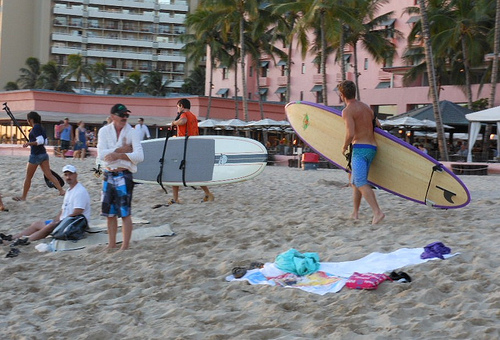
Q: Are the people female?
A: No, they are both male and female.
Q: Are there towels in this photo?
A: Yes, there is a towel.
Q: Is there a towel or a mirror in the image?
A: Yes, there is a towel.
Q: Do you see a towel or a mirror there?
A: Yes, there is a towel.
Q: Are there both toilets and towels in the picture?
A: No, there is a towel but no toilets.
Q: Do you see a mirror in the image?
A: No, there are no mirrors.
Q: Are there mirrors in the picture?
A: No, there are no mirrors.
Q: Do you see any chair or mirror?
A: No, there are no mirrors or chairs.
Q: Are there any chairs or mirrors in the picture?
A: No, there are no mirrors or chairs.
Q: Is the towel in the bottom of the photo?
A: Yes, the towel is in the bottom of the image.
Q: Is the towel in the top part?
A: No, the towel is in the bottom of the image.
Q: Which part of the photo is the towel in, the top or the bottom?
A: The towel is in the bottom of the image.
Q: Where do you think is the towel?
A: The towel is on the sand.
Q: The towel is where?
A: The towel is on the sand.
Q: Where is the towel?
A: The towel is on the sand.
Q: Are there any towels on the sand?
A: Yes, there is a towel on the sand.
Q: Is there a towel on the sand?
A: Yes, there is a towel on the sand.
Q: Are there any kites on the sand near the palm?
A: No, there is a towel on the sand.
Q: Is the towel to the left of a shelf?
A: No, the towel is to the left of the bag.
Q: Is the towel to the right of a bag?
A: No, the towel is to the left of a bag.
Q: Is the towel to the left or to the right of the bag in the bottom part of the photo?
A: The towel is to the left of the bag.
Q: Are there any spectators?
A: No, there are no spectators.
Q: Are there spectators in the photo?
A: No, there are no spectators.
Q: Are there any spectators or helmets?
A: No, there are no spectators or helmets.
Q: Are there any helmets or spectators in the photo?
A: No, there are no spectators or helmets.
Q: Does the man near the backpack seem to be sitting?
A: Yes, the man is sitting.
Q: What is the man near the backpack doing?
A: The man is sitting.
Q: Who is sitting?
A: The man is sitting.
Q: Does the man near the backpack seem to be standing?
A: No, the man is sitting.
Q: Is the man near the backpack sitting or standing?
A: The man is sitting.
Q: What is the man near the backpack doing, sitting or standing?
A: The man is sitting.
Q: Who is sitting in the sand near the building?
A: The man is sitting in the sand.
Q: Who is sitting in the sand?
A: The man is sitting in the sand.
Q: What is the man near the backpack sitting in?
A: The man is sitting in the sand.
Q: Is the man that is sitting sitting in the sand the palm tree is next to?
A: Yes, the man is sitting in the sand.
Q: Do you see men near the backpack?
A: Yes, there is a man near the backpack.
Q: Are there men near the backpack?
A: Yes, there is a man near the backpack.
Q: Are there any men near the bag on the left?
A: Yes, there is a man near the backpack.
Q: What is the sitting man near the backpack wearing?
A: The man is wearing a hat.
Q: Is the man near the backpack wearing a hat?
A: Yes, the man is wearing a hat.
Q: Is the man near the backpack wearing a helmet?
A: No, the man is wearing a hat.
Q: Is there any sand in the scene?
A: Yes, there is sand.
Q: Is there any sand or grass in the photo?
A: Yes, there is sand.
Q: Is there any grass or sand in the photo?
A: Yes, there is sand.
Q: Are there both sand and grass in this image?
A: No, there is sand but no grass.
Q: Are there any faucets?
A: No, there are no faucets.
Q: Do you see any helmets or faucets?
A: No, there are no faucets or helmets.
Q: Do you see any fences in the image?
A: No, there are no fences.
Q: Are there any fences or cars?
A: No, there are no fences or cars.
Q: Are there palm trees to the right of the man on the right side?
A: Yes, there is a palm tree to the right of the man.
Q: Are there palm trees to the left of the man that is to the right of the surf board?
A: No, the palm tree is to the right of the man.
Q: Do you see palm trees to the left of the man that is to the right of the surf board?
A: No, the palm tree is to the right of the man.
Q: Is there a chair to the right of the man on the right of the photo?
A: No, there is a palm tree to the right of the man.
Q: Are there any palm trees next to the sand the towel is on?
A: Yes, there is a palm tree next to the sand.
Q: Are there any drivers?
A: No, there are no drivers.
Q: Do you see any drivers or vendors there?
A: No, there are no drivers or vendors.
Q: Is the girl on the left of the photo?
A: Yes, the girl is on the left of the image.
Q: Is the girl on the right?
A: No, the girl is on the left of the image.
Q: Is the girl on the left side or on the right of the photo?
A: The girl is on the left of the image.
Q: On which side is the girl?
A: The girl is on the left of the image.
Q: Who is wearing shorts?
A: The girl is wearing shorts.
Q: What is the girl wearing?
A: The girl is wearing shorts.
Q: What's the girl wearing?
A: The girl is wearing shorts.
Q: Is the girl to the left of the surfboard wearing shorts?
A: Yes, the girl is wearing shorts.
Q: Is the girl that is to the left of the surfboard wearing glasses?
A: No, the girl is wearing shorts.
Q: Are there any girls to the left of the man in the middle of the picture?
A: Yes, there is a girl to the left of the man.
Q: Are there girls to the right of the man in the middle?
A: No, the girl is to the left of the man.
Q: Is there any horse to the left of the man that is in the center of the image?
A: No, there is a girl to the left of the man.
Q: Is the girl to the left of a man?
A: Yes, the girl is to the left of a man.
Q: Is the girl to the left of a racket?
A: No, the girl is to the left of a man.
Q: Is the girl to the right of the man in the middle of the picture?
A: No, the girl is to the left of the man.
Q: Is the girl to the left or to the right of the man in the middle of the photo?
A: The girl is to the left of the man.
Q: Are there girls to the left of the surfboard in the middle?
A: Yes, there is a girl to the left of the surfboard.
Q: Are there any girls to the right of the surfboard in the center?
A: No, the girl is to the left of the surfboard.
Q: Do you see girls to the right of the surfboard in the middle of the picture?
A: No, the girl is to the left of the surfboard.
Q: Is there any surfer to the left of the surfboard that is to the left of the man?
A: No, there is a girl to the left of the surfboard.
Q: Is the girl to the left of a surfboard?
A: Yes, the girl is to the left of a surfboard.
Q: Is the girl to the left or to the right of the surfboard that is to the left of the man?
A: The girl is to the left of the surfboard.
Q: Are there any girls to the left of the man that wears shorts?
A: Yes, there is a girl to the left of the man.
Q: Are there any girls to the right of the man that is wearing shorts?
A: No, the girl is to the left of the man.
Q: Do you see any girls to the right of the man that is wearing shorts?
A: No, the girl is to the left of the man.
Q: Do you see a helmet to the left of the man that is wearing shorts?
A: No, there is a girl to the left of the man.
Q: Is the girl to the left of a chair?
A: No, the girl is to the left of a man.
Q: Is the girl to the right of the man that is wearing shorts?
A: No, the girl is to the left of the man.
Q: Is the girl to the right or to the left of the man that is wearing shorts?
A: The girl is to the left of the man.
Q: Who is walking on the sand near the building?
A: The girl is walking on the sand.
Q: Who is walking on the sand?
A: The girl is walking on the sand.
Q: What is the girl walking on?
A: The girl is walking on the sand.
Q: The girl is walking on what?
A: The girl is walking on the sand.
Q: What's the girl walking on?
A: The girl is walking on the sand.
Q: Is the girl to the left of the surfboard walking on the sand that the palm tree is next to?
A: Yes, the girl is walking on the sand.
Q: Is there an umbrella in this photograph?
A: Yes, there is an umbrella.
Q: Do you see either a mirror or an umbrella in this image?
A: Yes, there is an umbrella.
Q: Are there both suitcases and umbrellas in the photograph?
A: No, there is an umbrella but no suitcases.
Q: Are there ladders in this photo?
A: No, there are no ladders.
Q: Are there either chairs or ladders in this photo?
A: No, there are no ladders or chairs.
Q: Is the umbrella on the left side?
A: No, the umbrella is on the right of the image.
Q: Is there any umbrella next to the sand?
A: Yes, there is an umbrella next to the sand.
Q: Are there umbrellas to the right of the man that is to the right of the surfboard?
A: Yes, there is an umbrella to the right of the man.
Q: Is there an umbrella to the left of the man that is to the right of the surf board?
A: No, the umbrella is to the right of the man.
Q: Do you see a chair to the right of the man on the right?
A: No, there is an umbrella to the right of the man.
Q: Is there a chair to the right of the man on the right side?
A: No, there is an umbrella to the right of the man.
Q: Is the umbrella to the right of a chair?
A: No, the umbrella is to the right of a man.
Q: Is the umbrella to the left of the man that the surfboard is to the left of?
A: No, the umbrella is to the right of the man.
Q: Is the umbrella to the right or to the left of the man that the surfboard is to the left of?
A: The umbrella is to the right of the man.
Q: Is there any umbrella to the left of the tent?
A: Yes, there is an umbrella to the left of the tent.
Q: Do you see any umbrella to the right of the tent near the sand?
A: No, the umbrella is to the left of the tent.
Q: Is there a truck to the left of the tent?
A: No, there is an umbrella to the left of the tent.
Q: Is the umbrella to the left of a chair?
A: No, the umbrella is to the left of the tent.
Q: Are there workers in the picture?
A: No, there are no workers.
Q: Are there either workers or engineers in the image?
A: No, there are no workers or engineers.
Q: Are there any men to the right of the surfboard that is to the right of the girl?
A: Yes, there is a man to the right of the surf board.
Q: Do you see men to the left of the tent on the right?
A: Yes, there is a man to the left of the tent.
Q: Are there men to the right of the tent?
A: No, the man is to the left of the tent.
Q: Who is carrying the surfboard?
A: The man is carrying the surfboard.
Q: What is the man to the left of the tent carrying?
A: The man is carrying a surf board.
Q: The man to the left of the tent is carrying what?
A: The man is carrying a surf board.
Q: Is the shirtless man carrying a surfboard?
A: Yes, the man is carrying a surfboard.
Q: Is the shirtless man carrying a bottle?
A: No, the man is carrying a surfboard.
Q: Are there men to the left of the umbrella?
A: Yes, there is a man to the left of the umbrella.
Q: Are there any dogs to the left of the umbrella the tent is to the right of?
A: No, there is a man to the left of the umbrella.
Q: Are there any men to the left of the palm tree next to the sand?
A: Yes, there is a man to the left of the palm.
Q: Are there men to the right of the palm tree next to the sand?
A: No, the man is to the left of the palm tree.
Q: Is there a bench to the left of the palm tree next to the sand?
A: No, there is a man to the left of the palm tree.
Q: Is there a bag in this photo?
A: Yes, there is a bag.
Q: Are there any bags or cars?
A: Yes, there is a bag.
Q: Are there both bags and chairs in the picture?
A: No, there is a bag but no chairs.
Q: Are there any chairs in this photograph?
A: No, there are no chairs.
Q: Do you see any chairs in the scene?
A: No, there are no chairs.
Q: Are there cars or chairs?
A: No, there are no chairs or cars.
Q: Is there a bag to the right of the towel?
A: Yes, there is a bag to the right of the towel.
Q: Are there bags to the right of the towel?
A: Yes, there is a bag to the right of the towel.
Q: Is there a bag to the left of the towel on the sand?
A: No, the bag is to the right of the towel.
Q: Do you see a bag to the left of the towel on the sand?
A: No, the bag is to the right of the towel.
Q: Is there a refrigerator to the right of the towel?
A: No, there is a bag to the right of the towel.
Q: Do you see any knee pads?
A: No, there are no knee pads.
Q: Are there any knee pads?
A: No, there are no knee pads.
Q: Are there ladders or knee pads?
A: No, there are no knee pads or ladders.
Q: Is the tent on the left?
A: No, the tent is on the right of the image.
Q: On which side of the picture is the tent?
A: The tent is on the right of the image.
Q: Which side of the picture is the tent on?
A: The tent is on the right of the image.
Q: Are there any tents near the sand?
A: Yes, there is a tent near the sand.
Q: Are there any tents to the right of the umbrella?
A: Yes, there is a tent to the right of the umbrella.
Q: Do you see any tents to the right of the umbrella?
A: Yes, there is a tent to the right of the umbrella.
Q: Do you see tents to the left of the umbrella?
A: No, the tent is to the right of the umbrella.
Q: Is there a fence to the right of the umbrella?
A: No, there is a tent to the right of the umbrella.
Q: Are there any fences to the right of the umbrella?
A: No, there is a tent to the right of the umbrella.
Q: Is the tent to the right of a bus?
A: No, the tent is to the right of the umbrella.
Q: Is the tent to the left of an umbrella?
A: No, the tent is to the right of an umbrella.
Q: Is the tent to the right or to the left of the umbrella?
A: The tent is to the right of the umbrella.